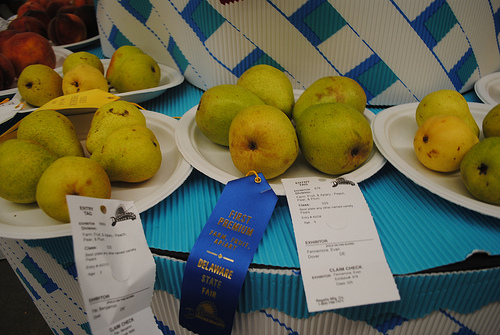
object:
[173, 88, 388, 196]
plate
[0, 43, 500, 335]
table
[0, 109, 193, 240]
plate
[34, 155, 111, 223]
pear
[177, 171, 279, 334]
ribbon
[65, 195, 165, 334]
tag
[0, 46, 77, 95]
plate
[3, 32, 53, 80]
peach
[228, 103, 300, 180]
pear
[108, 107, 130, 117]
bruising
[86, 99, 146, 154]
pear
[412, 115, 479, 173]
pear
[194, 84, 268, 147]
pear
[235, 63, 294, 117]
pear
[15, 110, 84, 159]
pear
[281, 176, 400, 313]
tag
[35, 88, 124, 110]
award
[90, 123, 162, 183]
pear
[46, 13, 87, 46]
peach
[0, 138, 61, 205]
pear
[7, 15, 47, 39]
peach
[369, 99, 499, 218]
plate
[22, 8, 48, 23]
peach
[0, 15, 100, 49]
plate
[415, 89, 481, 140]
pear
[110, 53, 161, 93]
pear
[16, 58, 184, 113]
plate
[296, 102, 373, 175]
pear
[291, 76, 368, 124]
pear